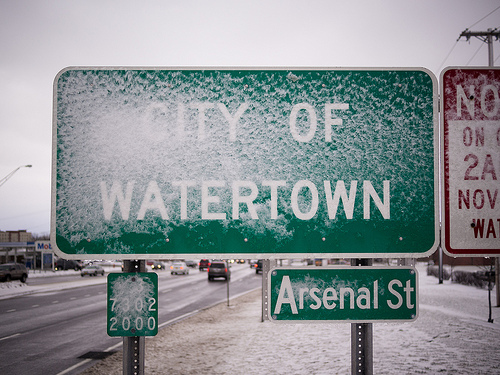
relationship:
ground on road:
[11, 267, 498, 374] [3, 257, 268, 374]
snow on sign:
[241, 324, 323, 358] [16, 42, 471, 310]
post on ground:
[346, 254, 381, 368] [6, 285, 498, 367]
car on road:
[191, 260, 241, 279] [6, 259, 238, 373]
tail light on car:
[178, 264, 185, 269] [170, 263, 188, 273]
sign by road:
[366, 52, 498, 247] [4, 277, 255, 360]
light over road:
[20, 155, 37, 181] [0, 264, 265, 374]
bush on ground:
[424, 261, 452, 283] [11, 267, 498, 374]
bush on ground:
[445, 264, 497, 289] [11, 267, 498, 374]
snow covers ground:
[79, 285, 500, 374] [11, 267, 498, 374]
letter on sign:
[141, 97, 168, 152] [44, 56, 446, 273]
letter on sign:
[169, 97, 191, 152] [44, 56, 446, 273]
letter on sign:
[213, 99, 252, 147] [44, 56, 446, 273]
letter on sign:
[219, 99, 252, 146] [44, 56, 446, 273]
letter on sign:
[96, 177, 137, 227] [18, 51, 449, 278]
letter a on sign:
[140, 183, 174, 229] [47, 65, 441, 266]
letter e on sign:
[199, 177, 227, 220] [44, 56, 446, 273]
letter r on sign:
[228, 176, 263, 218] [204, 257, 438, 349]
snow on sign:
[61, 73, 414, 173] [58, 75, 435, 248]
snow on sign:
[50, 68, 435, 243] [47, 65, 441, 261]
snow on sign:
[50, 68, 435, 243] [44, 56, 446, 273]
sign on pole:
[264, 263, 423, 325] [344, 255, 382, 374]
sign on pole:
[264, 263, 423, 325] [112, 247, 150, 372]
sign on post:
[47, 65, 441, 261] [346, 254, 381, 373]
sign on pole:
[47, 65, 441, 261] [116, 257, 144, 369]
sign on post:
[264, 263, 422, 323] [346, 254, 381, 373]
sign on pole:
[102, 267, 160, 337] [116, 257, 144, 369]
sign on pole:
[47, 65, 441, 266] [350, 317, 376, 374]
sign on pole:
[47, 65, 441, 266] [120, 334, 151, 374]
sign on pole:
[264, 263, 423, 325] [350, 317, 376, 374]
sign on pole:
[102, 267, 160, 337] [120, 334, 151, 374]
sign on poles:
[47, 65, 441, 261] [111, 324, 163, 374]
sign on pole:
[47, 65, 441, 261] [347, 257, 377, 372]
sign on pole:
[264, 263, 422, 323] [347, 257, 377, 372]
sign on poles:
[102, 267, 160, 337] [111, 324, 163, 374]